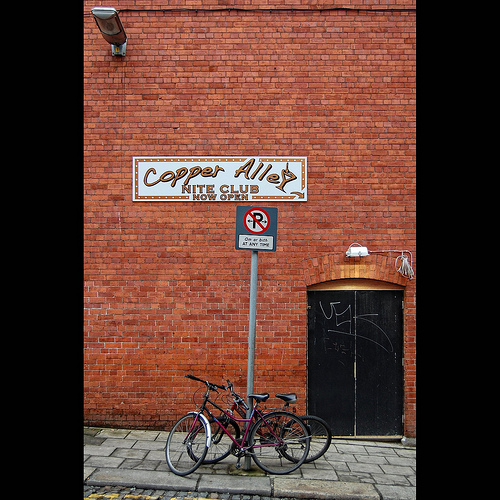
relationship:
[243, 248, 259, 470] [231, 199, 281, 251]
pole has a sign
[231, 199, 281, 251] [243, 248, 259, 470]
sign on pole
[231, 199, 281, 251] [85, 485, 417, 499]
sign for a street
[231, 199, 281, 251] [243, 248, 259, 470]
sign with a pole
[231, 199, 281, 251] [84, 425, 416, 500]
sign on sidewalk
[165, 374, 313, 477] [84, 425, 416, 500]
bike are on sidewalk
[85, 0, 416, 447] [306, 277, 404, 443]
building has a door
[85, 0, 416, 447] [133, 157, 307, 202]
building has a sign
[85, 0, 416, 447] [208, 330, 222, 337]
building made of brick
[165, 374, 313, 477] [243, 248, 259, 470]
bike tied to a pole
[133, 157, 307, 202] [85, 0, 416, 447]
sign on building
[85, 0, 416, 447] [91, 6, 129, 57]
building has a light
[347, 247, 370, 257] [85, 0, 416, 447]
light on building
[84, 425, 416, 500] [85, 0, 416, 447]
sidewalk in front of a building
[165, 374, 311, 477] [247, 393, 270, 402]
bike has a seat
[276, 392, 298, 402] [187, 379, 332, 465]
seat on bike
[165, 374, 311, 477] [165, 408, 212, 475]
bike has a wheel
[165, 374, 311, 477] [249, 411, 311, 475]
bike has a wheel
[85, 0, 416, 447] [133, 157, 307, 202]
night club named copper alley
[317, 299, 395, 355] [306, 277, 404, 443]
graffiti on door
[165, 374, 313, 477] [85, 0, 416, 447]
bike are in front of building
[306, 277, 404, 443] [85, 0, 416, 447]
door for building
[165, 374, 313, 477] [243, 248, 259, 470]
bike are tied to a pole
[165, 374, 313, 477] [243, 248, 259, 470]
bike are near a pole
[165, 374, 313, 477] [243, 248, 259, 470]
bike are on pole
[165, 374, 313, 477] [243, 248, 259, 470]
bike are on a pole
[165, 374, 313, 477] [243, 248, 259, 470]
bike are near pole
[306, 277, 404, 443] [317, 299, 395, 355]
door has graffiti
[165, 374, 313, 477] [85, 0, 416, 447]
bike are outside of building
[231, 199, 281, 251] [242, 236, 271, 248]
sign says no parking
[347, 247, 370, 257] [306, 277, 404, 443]
light above door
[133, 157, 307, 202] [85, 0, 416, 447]
sign for building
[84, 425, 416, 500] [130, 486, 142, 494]
sidewalk made of stone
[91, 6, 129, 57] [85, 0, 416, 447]
light attached to a building